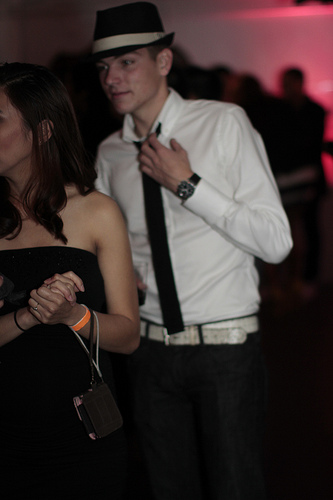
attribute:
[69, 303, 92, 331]
bracelet — orange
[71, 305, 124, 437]
cellphone case — hanging, small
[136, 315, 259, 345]
belt — white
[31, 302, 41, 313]
ring — metal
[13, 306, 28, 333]
rubber band — black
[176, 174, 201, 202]
watch — black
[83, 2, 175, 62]
hat — black, tan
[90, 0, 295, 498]
boy — dressed, thin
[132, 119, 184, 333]
tie — black, long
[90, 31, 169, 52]
ribbon — tan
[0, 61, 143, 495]
girl — dressed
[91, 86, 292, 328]
shirt — white, button down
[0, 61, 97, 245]
hair — brown